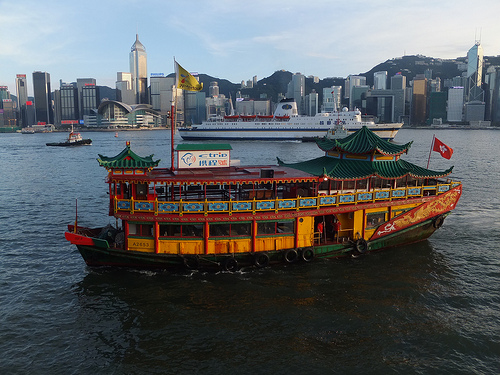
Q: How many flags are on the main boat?
A: Two.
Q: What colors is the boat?
A: Yellow, blue, red and green.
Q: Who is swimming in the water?
A: No one.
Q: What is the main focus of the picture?
A: An oriental boat.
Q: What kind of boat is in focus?
A: A ferry.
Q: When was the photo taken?
A: Daytime.